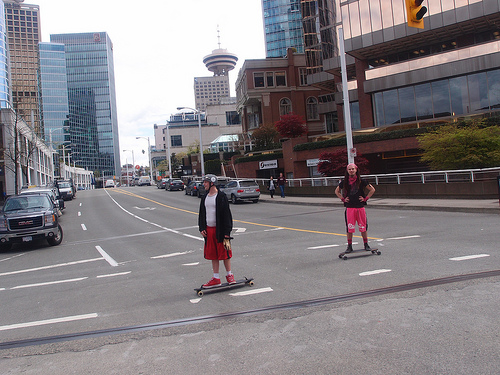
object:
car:
[0, 192, 63, 245]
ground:
[0, 187, 500, 375]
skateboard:
[338, 248, 381, 260]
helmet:
[202, 174, 217, 185]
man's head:
[203, 174, 218, 190]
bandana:
[346, 163, 357, 169]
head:
[347, 163, 358, 176]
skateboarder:
[194, 275, 256, 296]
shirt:
[339, 178, 371, 208]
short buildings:
[1, 13, 91, 201]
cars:
[18, 187, 64, 220]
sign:
[259, 160, 277, 170]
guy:
[197, 174, 236, 289]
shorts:
[203, 225, 233, 260]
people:
[267, 176, 277, 198]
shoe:
[225, 273, 236, 285]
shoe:
[202, 277, 221, 288]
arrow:
[133, 205, 156, 210]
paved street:
[101, 186, 378, 241]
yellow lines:
[105, 185, 382, 240]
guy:
[334, 162, 375, 253]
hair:
[343, 163, 361, 193]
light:
[404, 0, 425, 29]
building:
[299, 0, 500, 173]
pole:
[217, 24, 221, 48]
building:
[192, 22, 239, 110]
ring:
[202, 52, 240, 72]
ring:
[207, 62, 235, 72]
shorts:
[343, 207, 368, 232]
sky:
[116, 2, 173, 61]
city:
[0, 0, 500, 375]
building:
[49, 31, 121, 187]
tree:
[0, 100, 55, 196]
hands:
[358, 195, 366, 202]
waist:
[344, 201, 365, 208]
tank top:
[203, 192, 216, 227]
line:
[94, 245, 120, 267]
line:
[81, 223, 88, 230]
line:
[78, 211, 82, 217]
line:
[79, 202, 82, 206]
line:
[103, 187, 205, 242]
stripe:
[226, 250, 232, 259]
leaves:
[275, 111, 309, 137]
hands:
[343, 195, 350, 203]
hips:
[345, 204, 365, 211]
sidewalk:
[0, 176, 73, 372]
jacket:
[198, 190, 233, 246]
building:
[235, 48, 309, 185]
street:
[126, 158, 500, 201]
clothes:
[198, 190, 233, 260]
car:
[219, 178, 261, 204]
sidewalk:
[248, 181, 500, 210]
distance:
[0, 2, 262, 209]